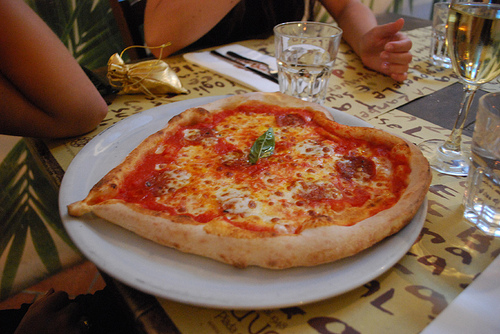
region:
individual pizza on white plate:
[62, 94, 431, 268]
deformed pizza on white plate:
[75, 90, 432, 271]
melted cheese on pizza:
[133, 113, 397, 242]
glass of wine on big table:
[423, 3, 498, 174]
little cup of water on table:
[280, 20, 341, 99]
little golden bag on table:
[107, 48, 182, 105]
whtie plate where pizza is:
[60, 84, 427, 316]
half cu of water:
[457, 83, 498, 248]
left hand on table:
[332, 0, 417, 89]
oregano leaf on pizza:
[246, 127, 277, 167]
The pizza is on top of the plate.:
[105, 90, 410, 282]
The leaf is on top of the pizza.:
[234, 122, 301, 178]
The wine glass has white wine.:
[444, 2, 497, 155]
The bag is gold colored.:
[99, 33, 191, 99]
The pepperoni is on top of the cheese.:
[320, 142, 389, 201]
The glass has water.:
[264, 13, 351, 108]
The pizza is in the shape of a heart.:
[60, 73, 437, 280]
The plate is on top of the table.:
[47, 96, 417, 332]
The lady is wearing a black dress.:
[197, 0, 342, 53]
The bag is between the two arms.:
[19, 2, 231, 111]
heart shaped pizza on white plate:
[53, 92, 435, 280]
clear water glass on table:
[251, 4, 351, 106]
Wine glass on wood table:
[426, 1, 497, 193]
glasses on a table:
[427, 0, 497, 240]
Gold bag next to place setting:
[101, 10, 344, 100]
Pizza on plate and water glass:
[56, 21, 439, 317]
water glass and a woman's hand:
[274, 0, 417, 101]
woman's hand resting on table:
[308, 1, 450, 111]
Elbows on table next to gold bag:
[2, 1, 233, 140]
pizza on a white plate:
[59, 93, 431, 305]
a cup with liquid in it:
[271, 18, 340, 98]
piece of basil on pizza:
[249, 124, 275, 162]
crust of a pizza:
[69, 200, 421, 269]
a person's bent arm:
[1, 0, 104, 142]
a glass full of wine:
[418, 0, 498, 182]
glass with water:
[464, 88, 499, 233]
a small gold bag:
[104, 40, 185, 96]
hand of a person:
[360, 19, 412, 81]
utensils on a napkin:
[184, 43, 290, 93]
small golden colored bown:
[95, 23, 183, 96]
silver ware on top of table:
[220, 38, 275, 85]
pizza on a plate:
[100, 89, 400, 271]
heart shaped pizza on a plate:
[84, 86, 412, 285]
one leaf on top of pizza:
[231, 128, 286, 177]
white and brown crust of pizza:
[265, 245, 311, 262]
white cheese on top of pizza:
[171, 119, 301, 221]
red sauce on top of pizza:
[126, 146, 203, 204]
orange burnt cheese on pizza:
[209, 173, 274, 214]